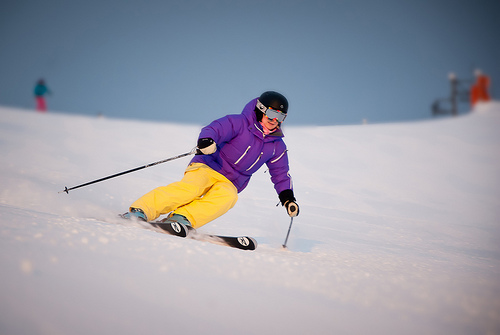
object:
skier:
[35, 78, 51, 112]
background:
[1, 1, 500, 122]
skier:
[471, 70, 490, 105]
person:
[130, 90, 299, 226]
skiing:
[62, 145, 299, 253]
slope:
[298, 102, 441, 319]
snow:
[318, 152, 483, 311]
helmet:
[257, 91, 288, 113]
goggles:
[266, 109, 286, 122]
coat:
[191, 115, 299, 192]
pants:
[128, 163, 238, 227]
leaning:
[64, 91, 299, 250]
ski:
[127, 222, 188, 237]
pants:
[37, 97, 46, 111]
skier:
[63, 91, 298, 253]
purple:
[213, 129, 235, 170]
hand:
[285, 201, 299, 216]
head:
[255, 91, 288, 129]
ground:
[3, 235, 494, 329]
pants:
[470, 74, 490, 101]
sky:
[7, 2, 476, 73]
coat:
[34, 85, 46, 96]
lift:
[433, 72, 472, 117]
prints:
[29, 210, 71, 219]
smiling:
[268, 122, 276, 126]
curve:
[0, 105, 481, 127]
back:
[190, 114, 243, 164]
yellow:
[189, 177, 227, 213]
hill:
[382, 102, 500, 203]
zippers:
[234, 146, 250, 164]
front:
[221, 117, 274, 193]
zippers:
[246, 153, 263, 171]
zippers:
[271, 149, 287, 163]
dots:
[98, 237, 108, 242]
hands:
[197, 139, 217, 154]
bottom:
[190, 236, 257, 251]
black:
[163, 223, 170, 228]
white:
[170, 222, 181, 232]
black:
[231, 240, 237, 245]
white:
[237, 237, 249, 246]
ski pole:
[62, 145, 200, 193]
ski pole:
[282, 216, 296, 247]